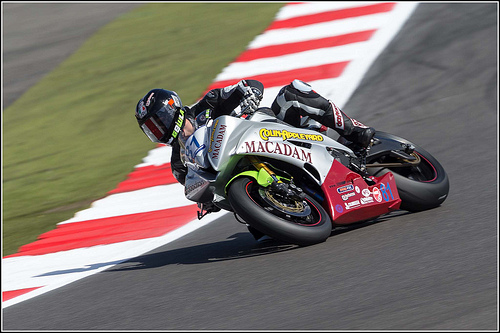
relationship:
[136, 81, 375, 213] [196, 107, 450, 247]
man on a motorcycle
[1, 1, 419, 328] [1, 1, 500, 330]
stripes on a track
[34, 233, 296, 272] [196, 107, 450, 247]
shadow of motorcycle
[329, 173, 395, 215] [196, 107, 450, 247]
decals on a motorcycle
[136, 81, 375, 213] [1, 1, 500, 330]
man on a track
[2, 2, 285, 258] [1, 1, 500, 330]
grass near a track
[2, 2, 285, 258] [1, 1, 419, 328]
grass near stripes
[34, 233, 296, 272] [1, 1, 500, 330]
shadow on a track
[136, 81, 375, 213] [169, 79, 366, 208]
man in a suit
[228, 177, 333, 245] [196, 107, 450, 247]
tire on a motorcycle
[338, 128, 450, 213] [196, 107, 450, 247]
tire on a motorcycle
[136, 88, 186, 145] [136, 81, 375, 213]
helmet on man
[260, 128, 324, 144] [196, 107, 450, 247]
word on motorcycle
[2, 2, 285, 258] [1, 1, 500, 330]
grass near track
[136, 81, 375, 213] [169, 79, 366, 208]
man in a uniform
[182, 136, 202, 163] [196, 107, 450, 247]
number on motorcycle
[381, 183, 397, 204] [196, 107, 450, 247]
number on motorcycle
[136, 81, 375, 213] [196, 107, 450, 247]
man on motorcycle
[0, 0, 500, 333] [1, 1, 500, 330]
scene at track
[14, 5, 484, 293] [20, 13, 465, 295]
scene during day